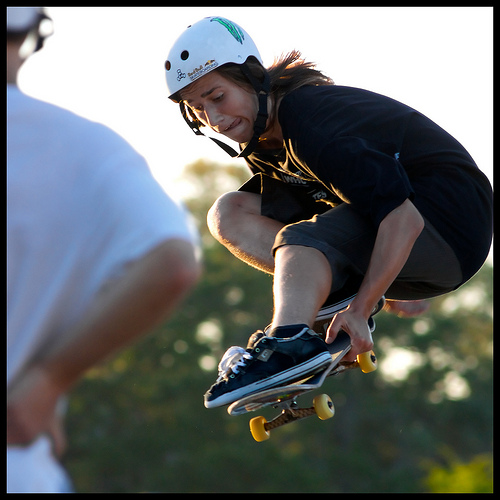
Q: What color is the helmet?
A: White.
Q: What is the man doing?
A: Jumping.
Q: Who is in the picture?
A: A man.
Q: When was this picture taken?
A: Daytime.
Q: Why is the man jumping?
A: He is skateboarding.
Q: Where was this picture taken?
A: A skate park.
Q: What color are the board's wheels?
A: Yellow.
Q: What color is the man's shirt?
A: Black.